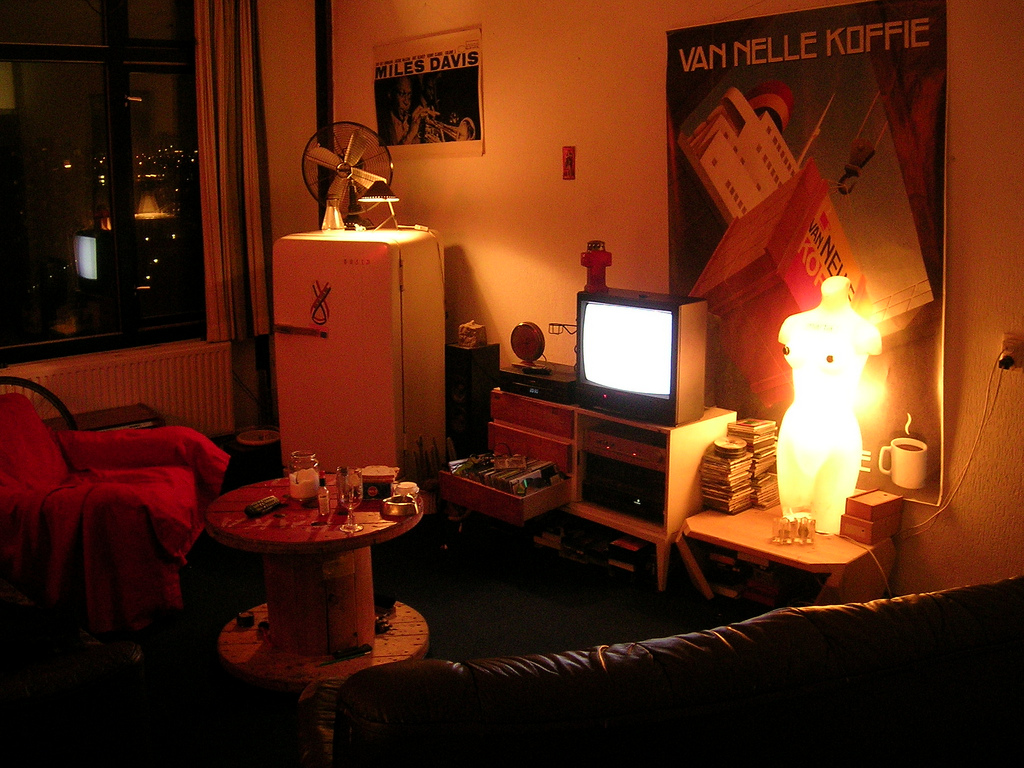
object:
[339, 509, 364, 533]
case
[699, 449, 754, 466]
case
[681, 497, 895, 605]
table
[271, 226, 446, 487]
refrigerator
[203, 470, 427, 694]
table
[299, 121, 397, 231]
fan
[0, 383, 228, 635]
chair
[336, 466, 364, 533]
wine glass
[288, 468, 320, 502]
candle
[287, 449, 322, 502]
jar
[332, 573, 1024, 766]
couch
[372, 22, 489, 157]
poster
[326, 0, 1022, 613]
wall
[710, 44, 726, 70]
letter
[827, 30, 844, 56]
letter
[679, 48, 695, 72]
letter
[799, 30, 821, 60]
letter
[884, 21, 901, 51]
letter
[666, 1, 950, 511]
sign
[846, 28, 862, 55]
letter